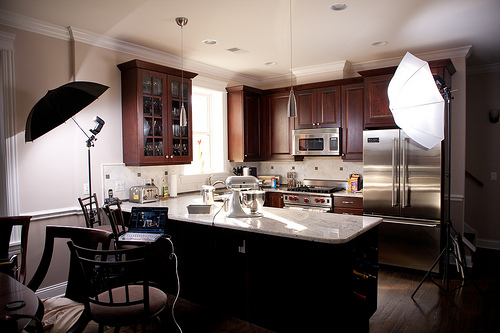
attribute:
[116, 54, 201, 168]
cabinet — fronted, wall, wood, glass, china, mounted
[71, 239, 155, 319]
back — curved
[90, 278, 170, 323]
seat — upholstered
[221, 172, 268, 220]
mixer — white, electric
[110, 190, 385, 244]
counter — white, marble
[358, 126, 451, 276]
fridge — steel, silver, stainless steel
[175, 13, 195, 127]
light — hanging, pendant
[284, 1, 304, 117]
light — hanging, pendant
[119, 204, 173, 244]
laptop — sitting, resting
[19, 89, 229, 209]
light — white, umbrella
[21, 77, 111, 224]
umbrella — black, lighting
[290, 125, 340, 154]
microwave — built in, stainless steel, here, space saver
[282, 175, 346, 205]
stove — stainless steel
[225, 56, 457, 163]
cabinets — wood, brown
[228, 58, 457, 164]
wood — dark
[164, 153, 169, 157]
knob — round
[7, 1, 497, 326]
kitchen — here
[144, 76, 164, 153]
window — glass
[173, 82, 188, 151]
window — glass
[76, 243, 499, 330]
floor — wooden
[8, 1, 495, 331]
shoot — set, photo, professional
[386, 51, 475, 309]
lighting — photo shoot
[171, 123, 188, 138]
glasswear — kept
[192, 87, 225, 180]
view — window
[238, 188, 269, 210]
bowl — stainless steel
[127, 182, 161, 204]
toaster — here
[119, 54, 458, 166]
cabinetry — wood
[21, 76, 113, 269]
source — light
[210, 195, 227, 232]
cord — electrical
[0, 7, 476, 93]
molding — decorative, white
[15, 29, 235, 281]
wall — white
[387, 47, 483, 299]
umbrella — white, lighting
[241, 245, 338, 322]
cabinet — black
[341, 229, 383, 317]
cabinet — black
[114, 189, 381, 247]
granite — white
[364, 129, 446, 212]
doors — french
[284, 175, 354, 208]
range — gas, stainless steel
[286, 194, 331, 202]
dials — red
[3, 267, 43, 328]
table — wooden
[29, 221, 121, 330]
chair — dining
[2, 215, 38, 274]
chair — dining